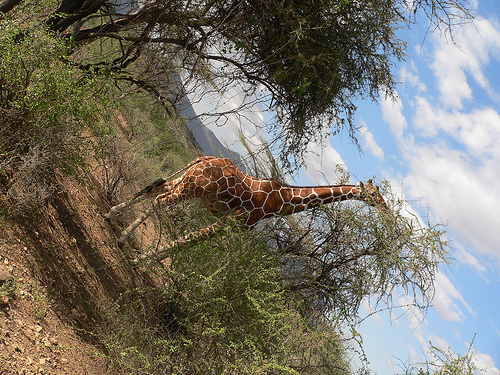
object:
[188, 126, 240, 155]
mountain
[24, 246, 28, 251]
stones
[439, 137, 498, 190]
clouds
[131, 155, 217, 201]
tail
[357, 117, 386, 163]
clouds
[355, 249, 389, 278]
leaves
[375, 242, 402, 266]
leaves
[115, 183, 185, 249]
legs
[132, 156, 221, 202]
tail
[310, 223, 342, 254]
branches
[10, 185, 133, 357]
shadows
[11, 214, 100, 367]
ground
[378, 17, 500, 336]
sky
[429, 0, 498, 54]
clouds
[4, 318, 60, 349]
rocks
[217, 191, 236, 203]
spot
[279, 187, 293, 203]
spot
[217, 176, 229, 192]
spot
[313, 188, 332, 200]
spot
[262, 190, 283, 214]
spot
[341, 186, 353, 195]
spot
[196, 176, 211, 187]
spot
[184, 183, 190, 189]
spot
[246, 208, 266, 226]
spot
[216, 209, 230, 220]
spot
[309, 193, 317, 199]
spot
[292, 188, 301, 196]
spot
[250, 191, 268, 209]
spot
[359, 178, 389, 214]
head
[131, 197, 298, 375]
plants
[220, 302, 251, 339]
leaves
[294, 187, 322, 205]
fur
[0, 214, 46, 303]
sand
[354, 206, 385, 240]
leaves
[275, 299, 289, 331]
leaves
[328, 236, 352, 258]
leaves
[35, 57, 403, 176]
tree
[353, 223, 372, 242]
leaves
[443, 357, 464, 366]
leaves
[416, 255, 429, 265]
leaves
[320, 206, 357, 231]
leaves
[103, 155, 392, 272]
giraffe